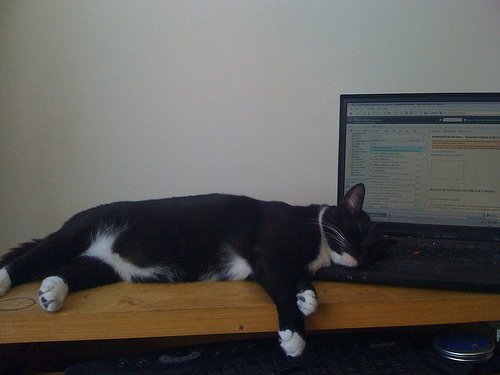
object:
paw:
[276, 327, 307, 358]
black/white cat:
[0, 182, 405, 360]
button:
[407, 247, 420, 257]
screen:
[343, 102, 500, 230]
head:
[324, 181, 402, 273]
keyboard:
[314, 229, 500, 293]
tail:
[2, 236, 51, 268]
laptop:
[311, 90, 500, 295]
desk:
[1, 276, 500, 347]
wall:
[0, 1, 500, 258]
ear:
[339, 180, 371, 216]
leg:
[259, 253, 303, 324]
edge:
[0, 293, 500, 346]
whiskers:
[306, 213, 350, 253]